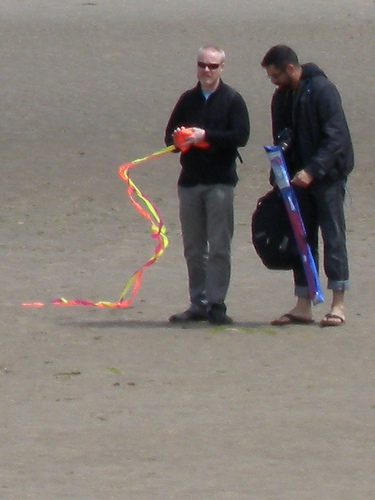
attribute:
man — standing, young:
[250, 39, 358, 329]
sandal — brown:
[269, 310, 317, 329]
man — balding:
[156, 43, 252, 330]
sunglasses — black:
[195, 57, 223, 73]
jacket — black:
[269, 64, 357, 190]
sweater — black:
[160, 75, 250, 190]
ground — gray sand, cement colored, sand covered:
[2, 2, 372, 497]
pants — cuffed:
[283, 168, 361, 300]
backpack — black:
[248, 179, 323, 272]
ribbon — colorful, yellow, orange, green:
[19, 141, 182, 315]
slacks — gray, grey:
[176, 178, 239, 312]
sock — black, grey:
[169, 301, 208, 322]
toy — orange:
[168, 122, 211, 156]